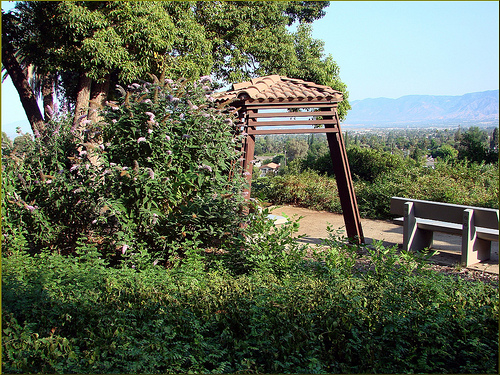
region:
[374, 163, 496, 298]
a bench on a sidewalk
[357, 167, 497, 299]
a cement bench on a sidewalk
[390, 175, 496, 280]
a cement bench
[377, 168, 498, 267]
a cement bench during the day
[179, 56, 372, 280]
a tall canopy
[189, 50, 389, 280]
a brown canopy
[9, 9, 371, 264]
trees next to the canopy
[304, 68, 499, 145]
mountains in the distance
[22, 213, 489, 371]
a lot of bushes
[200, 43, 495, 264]
canopy next to the bench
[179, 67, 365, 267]
brown structure outdoors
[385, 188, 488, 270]
gray bench on ground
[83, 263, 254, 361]
green bushes next to bench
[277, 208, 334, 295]
brown floor beneath structure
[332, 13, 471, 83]
blue sky above land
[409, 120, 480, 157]
green trees in distance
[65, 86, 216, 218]
bright flowers next to structure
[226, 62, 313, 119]
roof on top of structure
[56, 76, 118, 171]
brown branches of trees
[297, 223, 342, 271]
shadow on the ground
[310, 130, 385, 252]
brown pillar on ground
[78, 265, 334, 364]
green bush next to structure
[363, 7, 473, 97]
blue sky in above land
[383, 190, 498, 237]
back of the bench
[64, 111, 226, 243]
flowers next to structure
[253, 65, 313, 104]
roof of the structure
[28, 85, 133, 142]
brown branches of trees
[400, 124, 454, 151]
trees in the background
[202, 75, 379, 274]
Pergola standing on sidewalk.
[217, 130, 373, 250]
Support legs on pergola.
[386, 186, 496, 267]
Bench sitting on sidewalk.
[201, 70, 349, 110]
Tiled roof on a pergola.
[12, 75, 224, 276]
Flowering bush growing next to pergola.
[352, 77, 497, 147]
Mountains rising in the distance.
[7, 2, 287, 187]
Trees growing next to pergola.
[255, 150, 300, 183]
House sitting down hill from pergola.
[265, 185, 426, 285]
Sidewalk running through garden.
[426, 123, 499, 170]
Trees growing downhill next to homes.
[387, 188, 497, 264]
A bench along a path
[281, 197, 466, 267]
A concrete pathway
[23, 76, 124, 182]
A grouping of tree trunks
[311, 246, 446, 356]
Green plants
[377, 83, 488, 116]
Mountains in the distance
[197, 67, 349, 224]
A covered shelter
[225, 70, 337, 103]
Tile shingles on a roof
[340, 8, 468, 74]
A pale blue sky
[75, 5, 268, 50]
The leafy green tops of trees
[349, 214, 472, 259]
The shadow of a bench on the ground